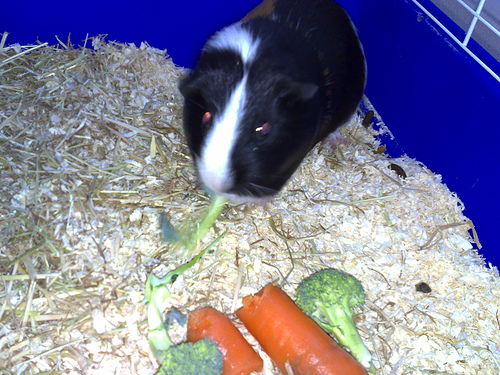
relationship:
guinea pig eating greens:
[175, 0, 370, 207] [150, 186, 229, 253]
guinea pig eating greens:
[175, 0, 370, 207] [140, 221, 236, 313]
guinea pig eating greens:
[175, 0, 370, 207] [288, 261, 383, 371]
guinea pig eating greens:
[175, 0, 370, 207] [135, 267, 230, 372]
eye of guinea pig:
[189, 102, 215, 129] [175, 0, 370, 207]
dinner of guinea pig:
[131, 198, 388, 368] [175, 0, 370, 207]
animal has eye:
[175, 2, 370, 205] [255, 122, 271, 135]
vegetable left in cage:
[145, 193, 373, 375] [0, 2, 499, 374]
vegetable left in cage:
[144, 201, 241, 285] [0, 2, 499, 374]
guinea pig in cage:
[175, 0, 370, 207] [0, 2, 499, 374]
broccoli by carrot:
[292, 267, 376, 367] [234, 284, 366, 372]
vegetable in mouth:
[145, 193, 373, 375] [210, 193, 240, 208]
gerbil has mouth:
[184, 5, 364, 193] [210, 193, 240, 208]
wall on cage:
[1, 0, 498, 272] [0, 2, 499, 374]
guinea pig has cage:
[175, 0, 370, 207] [0, 2, 499, 374]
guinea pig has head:
[175, 0, 370, 207] [173, 52, 314, 203]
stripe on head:
[194, 85, 251, 193] [173, 52, 314, 203]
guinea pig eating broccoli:
[175, 0, 370, 207] [292, 267, 376, 367]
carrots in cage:
[184, 280, 341, 372] [362, 0, 499, 178]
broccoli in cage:
[134, 260, 378, 373] [0, 2, 499, 374]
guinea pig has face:
[175, 0, 370, 207] [197, 100, 273, 181]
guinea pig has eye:
[175, 0, 370, 207] [256, 121, 271, 136]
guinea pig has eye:
[175, 0, 370, 207] [200, 112, 211, 122]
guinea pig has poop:
[175, 0, 370, 207] [379, 144, 441, 305]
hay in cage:
[3, 36, 200, 370] [0, 2, 499, 374]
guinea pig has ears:
[167, 2, 390, 199] [165, 71, 332, 110]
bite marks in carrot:
[232, 280, 278, 313] [173, 285, 371, 367]